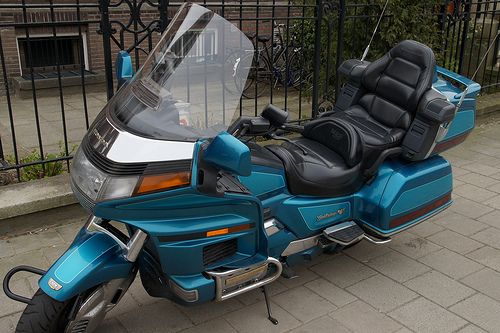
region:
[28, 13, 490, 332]
Bike on the road.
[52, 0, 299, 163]
Windshield on the bike.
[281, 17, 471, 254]
Seat on the bike.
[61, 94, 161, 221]
Light on the bike.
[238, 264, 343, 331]
Kick stand on the bike.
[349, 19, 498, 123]
Antenna on the bike.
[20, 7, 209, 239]
Fence in the background.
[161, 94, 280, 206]
Mirror on the bike.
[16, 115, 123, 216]
Grass on the ground.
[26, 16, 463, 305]
a blue motorcycle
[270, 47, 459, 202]
this motorcycle has two black seat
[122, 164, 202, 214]
orange lights on the motorcycle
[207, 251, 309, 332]
a kickstand on the motorbike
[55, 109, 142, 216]
a light on the front of the motorcycle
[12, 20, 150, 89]
a building in the background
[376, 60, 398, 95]
Black back on seat of bike.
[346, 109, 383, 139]
Seat on bike is black.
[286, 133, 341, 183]
Seat on bike is black.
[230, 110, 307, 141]
Black handle bar on bike.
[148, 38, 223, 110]
Clear windshield on front of bike.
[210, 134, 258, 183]
Blue mirror on front of bike.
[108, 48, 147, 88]
Blue mirror on front of bike.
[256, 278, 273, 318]
Black kickstand on bike.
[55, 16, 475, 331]
This is a motorcycle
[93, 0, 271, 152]
The motorcycle has a shield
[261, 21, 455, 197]
The motorcycle has two seats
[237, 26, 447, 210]
Two black leather seats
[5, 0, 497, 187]
Black gate and fence behind motorcycle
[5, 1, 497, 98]
Brick house in the background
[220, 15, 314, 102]
Two bicycles in the background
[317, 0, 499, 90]
Motorcycle has two antennas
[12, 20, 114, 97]
This is a cellar window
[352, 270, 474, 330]
A tile bricked gorund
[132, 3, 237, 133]
Windshield of the blue bike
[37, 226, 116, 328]
Front wheel of the motorcycle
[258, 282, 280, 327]
A motorcycle's brake pedal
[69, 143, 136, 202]
A motorcycle's front headlight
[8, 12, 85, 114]
Black fence near the motorcycle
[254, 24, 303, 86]
A couple of bicycle's in the background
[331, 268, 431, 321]
Brick tile under the motorcycle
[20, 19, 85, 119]
Black fence near the motorcycle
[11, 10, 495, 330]
the bike is teal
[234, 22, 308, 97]
the bike behind the black gate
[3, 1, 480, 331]
a blue motorcycle parked on the pavement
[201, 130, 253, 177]
the left rearview mirror on the motorcycle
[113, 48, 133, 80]
the right rearview mirror on the motorcycle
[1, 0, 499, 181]
the wrought iron fence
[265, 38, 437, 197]
the black leather seat of the motorcycle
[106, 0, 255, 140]
the windshield on the motorcycle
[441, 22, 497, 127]
a radio antenna on the motorcycle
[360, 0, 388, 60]
a radio antenna on the motorcycle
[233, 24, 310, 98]
a bicycle parked behind the fence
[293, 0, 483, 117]
green bushes behind the fence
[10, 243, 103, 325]
The front wheel on the scooter.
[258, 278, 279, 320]
The black kickstand on the bike.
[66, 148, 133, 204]
The front light on the scooter.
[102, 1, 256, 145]
The clear shield on the scooter.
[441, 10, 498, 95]
The right antenna on the scooter.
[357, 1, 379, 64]
The right antenna on the scooter.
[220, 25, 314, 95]
Two bicycles in the back.